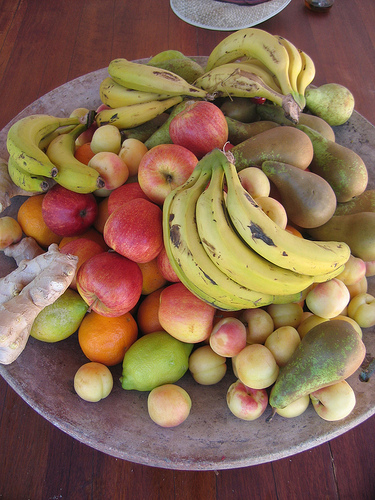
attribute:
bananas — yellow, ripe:
[161, 149, 348, 311]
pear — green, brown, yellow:
[265, 319, 367, 425]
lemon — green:
[120, 330, 196, 392]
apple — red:
[102, 197, 164, 264]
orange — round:
[77, 307, 141, 366]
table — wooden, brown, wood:
[1, 2, 370, 495]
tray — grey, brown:
[0, 54, 374, 473]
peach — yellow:
[73, 361, 115, 403]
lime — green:
[30, 288, 90, 342]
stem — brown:
[266, 406, 276, 421]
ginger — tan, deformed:
[0, 236, 79, 365]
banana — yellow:
[46, 122, 106, 193]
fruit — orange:
[18, 194, 61, 249]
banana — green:
[6, 114, 72, 178]